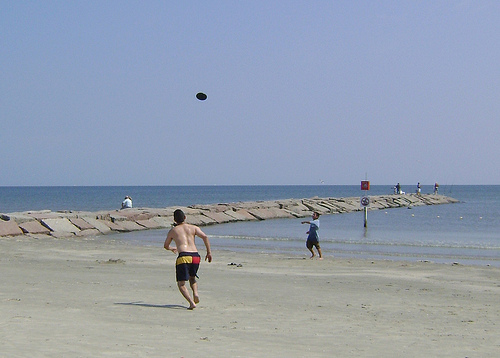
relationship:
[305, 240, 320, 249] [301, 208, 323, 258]
pants on boy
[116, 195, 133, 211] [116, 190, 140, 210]
person wearing white shirt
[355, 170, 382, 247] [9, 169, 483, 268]
pole sticking out of water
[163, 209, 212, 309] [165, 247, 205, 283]
boy wearing shorts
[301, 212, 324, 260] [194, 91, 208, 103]
boy playing frisbee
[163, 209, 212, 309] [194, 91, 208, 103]
boy playing frisbee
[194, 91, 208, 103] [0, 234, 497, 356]
frisbee on beach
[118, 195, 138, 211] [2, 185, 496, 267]
person on water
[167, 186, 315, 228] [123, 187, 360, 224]
structure on pier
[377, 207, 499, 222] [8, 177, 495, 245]
line on water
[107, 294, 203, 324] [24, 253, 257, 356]
shadow on sand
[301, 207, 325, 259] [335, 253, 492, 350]
boy on beach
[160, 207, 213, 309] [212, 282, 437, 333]
boy on sand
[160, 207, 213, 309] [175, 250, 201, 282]
boy on shorts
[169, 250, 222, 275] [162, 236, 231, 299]
stripe on shorts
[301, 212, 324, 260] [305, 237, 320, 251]
boy on pants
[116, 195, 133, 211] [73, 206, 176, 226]
person sits on rocks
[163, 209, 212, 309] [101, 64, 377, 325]
boy playing game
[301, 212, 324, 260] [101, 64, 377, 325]
boy playing game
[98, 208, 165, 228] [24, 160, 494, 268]
wall near water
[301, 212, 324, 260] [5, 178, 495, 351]
boy on beach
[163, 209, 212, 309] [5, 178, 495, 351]
boy on beach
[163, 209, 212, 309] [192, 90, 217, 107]
boy catching frisbee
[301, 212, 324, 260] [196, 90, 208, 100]
boy throwing frisbee